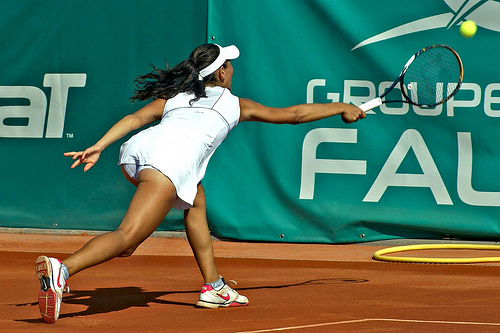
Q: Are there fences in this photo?
A: No, there are no fences.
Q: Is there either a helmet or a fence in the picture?
A: No, there are no fences or helmets.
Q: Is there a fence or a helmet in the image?
A: No, there are no fences or helmets.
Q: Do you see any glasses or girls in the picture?
A: No, there are no glasses or girls.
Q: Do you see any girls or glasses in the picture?
A: No, there are no glasses or girls.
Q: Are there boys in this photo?
A: No, there are no boys.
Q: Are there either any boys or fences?
A: No, there are no boys or fences.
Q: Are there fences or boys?
A: No, there are no boys or fences.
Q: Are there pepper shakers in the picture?
A: No, there are no pepper shakers.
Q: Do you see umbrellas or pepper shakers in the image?
A: No, there are no pepper shakers or umbrellas.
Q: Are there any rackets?
A: Yes, there is a racket.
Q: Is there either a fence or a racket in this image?
A: Yes, there is a racket.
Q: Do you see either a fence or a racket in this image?
A: Yes, there is a racket.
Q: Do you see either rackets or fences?
A: Yes, there is a racket.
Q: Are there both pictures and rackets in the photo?
A: Yes, there are both a racket and a picture.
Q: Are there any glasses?
A: No, there are no glasses.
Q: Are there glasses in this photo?
A: No, there are no glasses.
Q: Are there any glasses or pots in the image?
A: No, there are no glasses or pots.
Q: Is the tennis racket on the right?
A: Yes, the tennis racket is on the right of the image.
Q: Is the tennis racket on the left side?
A: No, the tennis racket is on the right of the image.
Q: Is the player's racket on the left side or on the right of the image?
A: The tennis racket is on the right of the image.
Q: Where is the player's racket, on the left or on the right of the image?
A: The tennis racket is on the right of the image.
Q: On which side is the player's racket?
A: The tennis racket is on the right of the image.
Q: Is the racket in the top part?
A: Yes, the racket is in the top of the image.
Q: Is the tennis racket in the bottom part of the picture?
A: No, the tennis racket is in the top of the image.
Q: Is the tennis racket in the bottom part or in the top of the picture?
A: The tennis racket is in the top of the image.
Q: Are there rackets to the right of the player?
A: Yes, there is a racket to the right of the player.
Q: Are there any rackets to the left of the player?
A: No, the racket is to the right of the player.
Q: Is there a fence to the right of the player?
A: No, there is a racket to the right of the player.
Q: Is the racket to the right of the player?
A: Yes, the racket is to the right of the player.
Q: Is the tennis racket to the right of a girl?
A: No, the tennis racket is to the right of the player.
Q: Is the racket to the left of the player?
A: No, the racket is to the right of the player.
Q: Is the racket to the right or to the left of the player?
A: The racket is to the right of the player.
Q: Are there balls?
A: Yes, there is a ball.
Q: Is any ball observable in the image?
A: Yes, there is a ball.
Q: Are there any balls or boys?
A: Yes, there is a ball.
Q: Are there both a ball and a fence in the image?
A: No, there is a ball but no fences.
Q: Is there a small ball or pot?
A: Yes, there is a small ball.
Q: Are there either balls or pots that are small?
A: Yes, the ball is small.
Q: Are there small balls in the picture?
A: Yes, there is a small ball.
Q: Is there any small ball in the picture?
A: Yes, there is a small ball.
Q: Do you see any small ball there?
A: Yes, there is a small ball.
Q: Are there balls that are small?
A: Yes, there is a ball that is small.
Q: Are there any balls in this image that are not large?
A: Yes, there is a small ball.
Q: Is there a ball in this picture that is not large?
A: Yes, there is a small ball.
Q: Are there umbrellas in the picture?
A: No, there are no umbrellas.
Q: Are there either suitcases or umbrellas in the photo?
A: No, there are no umbrellas or suitcases.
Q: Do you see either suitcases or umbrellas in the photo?
A: No, there are no umbrellas or suitcases.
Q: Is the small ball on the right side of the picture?
A: Yes, the ball is on the right of the image.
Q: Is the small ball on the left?
A: No, the ball is on the right of the image.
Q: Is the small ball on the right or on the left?
A: The ball is on the right of the image.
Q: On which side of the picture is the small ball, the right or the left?
A: The ball is on the right of the image.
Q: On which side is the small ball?
A: The ball is on the right of the image.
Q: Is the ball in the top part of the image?
A: Yes, the ball is in the top of the image.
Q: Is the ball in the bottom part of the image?
A: No, the ball is in the top of the image.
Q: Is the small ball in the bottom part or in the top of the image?
A: The ball is in the top of the image.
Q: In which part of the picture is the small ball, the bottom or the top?
A: The ball is in the top of the image.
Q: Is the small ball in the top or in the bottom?
A: The ball is in the top of the image.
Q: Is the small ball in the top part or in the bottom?
A: The ball is in the top of the image.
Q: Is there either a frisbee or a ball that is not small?
A: No, there is a ball but it is small.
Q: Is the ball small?
A: Yes, the ball is small.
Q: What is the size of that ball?
A: The ball is small.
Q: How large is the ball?
A: The ball is small.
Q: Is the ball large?
A: No, the ball is small.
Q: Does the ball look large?
A: No, the ball is small.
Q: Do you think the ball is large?
A: No, the ball is small.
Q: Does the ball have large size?
A: No, the ball is small.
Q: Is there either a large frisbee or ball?
A: No, there is a ball but it is small.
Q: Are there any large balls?
A: No, there is a ball but it is small.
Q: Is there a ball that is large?
A: No, there is a ball but it is small.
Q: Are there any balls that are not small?
A: No, there is a ball but it is small.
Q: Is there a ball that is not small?
A: No, there is a ball but it is small.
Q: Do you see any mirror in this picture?
A: No, there are no mirrors.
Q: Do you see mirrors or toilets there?
A: No, there are no mirrors or toilets.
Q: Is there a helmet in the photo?
A: No, there are no helmets.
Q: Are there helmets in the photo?
A: No, there are no helmets.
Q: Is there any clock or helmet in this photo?
A: No, there are no helmets or clocks.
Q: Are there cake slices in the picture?
A: No, there are no cake slices.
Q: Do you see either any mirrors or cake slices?
A: No, there are no cake slices or mirrors.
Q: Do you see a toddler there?
A: No, there are no toddlers.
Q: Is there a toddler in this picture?
A: No, there are no toddlers.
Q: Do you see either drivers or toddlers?
A: No, there are no toddlers or drivers.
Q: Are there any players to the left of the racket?
A: Yes, there is a player to the left of the racket.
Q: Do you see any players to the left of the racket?
A: Yes, there is a player to the left of the racket.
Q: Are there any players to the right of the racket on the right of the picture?
A: No, the player is to the left of the tennis racket.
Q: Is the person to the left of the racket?
A: Yes, the player is to the left of the racket.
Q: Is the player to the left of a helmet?
A: No, the player is to the left of the racket.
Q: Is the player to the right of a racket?
A: No, the player is to the left of a racket.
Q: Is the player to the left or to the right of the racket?
A: The player is to the left of the racket.